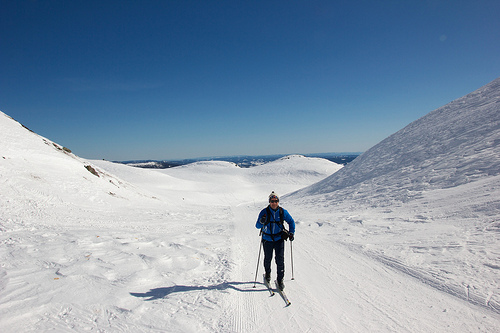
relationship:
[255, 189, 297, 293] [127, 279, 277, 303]
man has shadow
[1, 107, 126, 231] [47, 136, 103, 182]
hill has rocks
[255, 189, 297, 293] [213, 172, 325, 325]
man skiing on pathway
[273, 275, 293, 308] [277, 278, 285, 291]
ski attached on foot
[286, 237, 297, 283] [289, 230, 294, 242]
pole held in hand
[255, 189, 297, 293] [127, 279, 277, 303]
man casts shadow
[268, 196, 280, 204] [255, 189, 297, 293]
sunglasses on face of man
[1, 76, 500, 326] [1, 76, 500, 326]
snow covering ground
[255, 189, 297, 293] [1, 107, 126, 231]
man on base of hill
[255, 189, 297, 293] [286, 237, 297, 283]
man holding pole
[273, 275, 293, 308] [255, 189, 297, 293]
ski on foot of man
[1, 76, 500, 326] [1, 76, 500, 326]
snow laying on ground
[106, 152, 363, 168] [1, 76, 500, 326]
water behind snow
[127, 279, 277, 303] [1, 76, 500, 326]
shadow falls on snow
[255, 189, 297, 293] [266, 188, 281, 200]
man wearing cap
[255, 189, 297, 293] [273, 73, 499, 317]
man skiing on slope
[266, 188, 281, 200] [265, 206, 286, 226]
cap and chest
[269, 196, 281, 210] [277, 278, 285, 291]
face and foot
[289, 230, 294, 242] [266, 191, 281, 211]
hand and head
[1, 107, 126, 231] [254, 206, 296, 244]
hill and jacket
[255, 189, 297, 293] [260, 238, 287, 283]
man and pants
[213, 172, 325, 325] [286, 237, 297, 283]
pathway and pole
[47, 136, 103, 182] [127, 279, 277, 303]
rocks and shadow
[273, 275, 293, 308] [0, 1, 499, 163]
ski and sky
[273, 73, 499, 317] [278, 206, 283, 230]
slope and strap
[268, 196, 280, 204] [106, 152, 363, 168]
sunglasses and water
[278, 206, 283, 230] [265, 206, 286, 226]
strap across chest